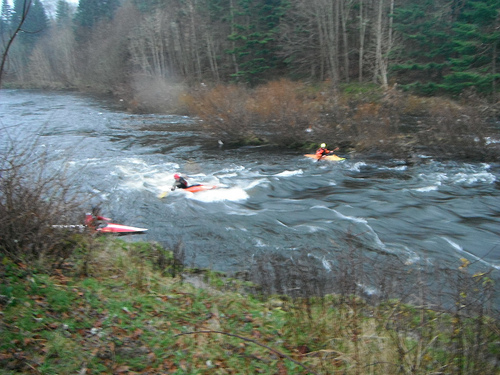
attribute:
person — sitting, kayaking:
[172, 174, 190, 193]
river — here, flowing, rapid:
[0, 87, 499, 316]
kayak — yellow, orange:
[305, 153, 346, 161]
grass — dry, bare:
[185, 81, 499, 160]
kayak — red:
[48, 222, 149, 234]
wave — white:
[69, 155, 305, 202]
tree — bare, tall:
[207, 3, 298, 89]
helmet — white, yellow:
[319, 142, 327, 148]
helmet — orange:
[173, 173, 181, 180]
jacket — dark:
[177, 178, 189, 189]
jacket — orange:
[317, 147, 329, 159]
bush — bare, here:
[1, 108, 110, 278]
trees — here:
[0, 0, 498, 99]